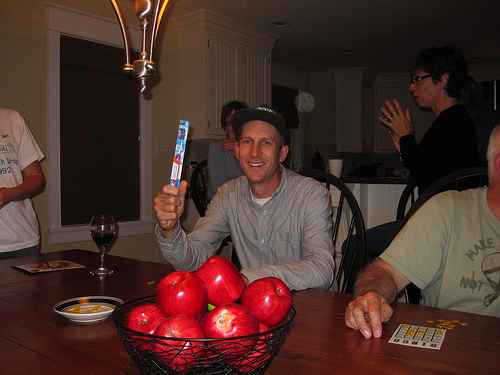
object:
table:
[47, 242, 349, 371]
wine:
[90, 229, 117, 248]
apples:
[151, 255, 291, 337]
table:
[260, 278, 379, 368]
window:
[58, 36, 141, 225]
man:
[150, 101, 339, 292]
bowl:
[112, 121, 296, 290]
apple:
[153, 269, 207, 318]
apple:
[190, 254, 244, 304]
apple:
[239, 274, 293, 325]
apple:
[123, 301, 163, 351]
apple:
[150, 313, 204, 370]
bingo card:
[386, 322, 448, 349]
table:
[0, 247, 499, 373]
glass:
[82, 216, 120, 281]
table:
[20, 248, 144, 292]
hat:
[232, 104, 300, 140]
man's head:
[232, 105, 294, 183]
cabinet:
[173, 8, 278, 141]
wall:
[113, 20, 258, 205]